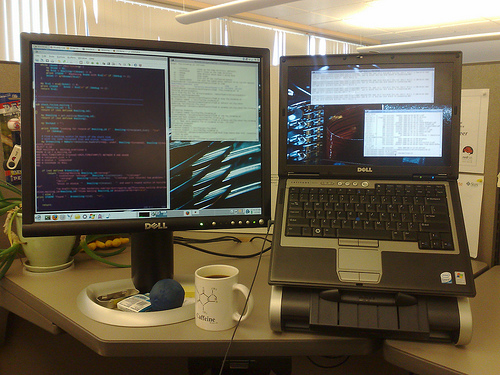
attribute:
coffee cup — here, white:
[194, 264, 254, 331]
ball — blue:
[149, 283, 182, 308]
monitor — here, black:
[20, 32, 272, 287]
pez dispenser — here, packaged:
[1, 92, 30, 185]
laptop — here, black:
[276, 54, 476, 294]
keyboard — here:
[286, 182, 451, 252]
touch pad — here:
[337, 249, 380, 270]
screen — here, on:
[291, 66, 447, 170]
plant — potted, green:
[3, 180, 132, 282]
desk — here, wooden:
[3, 214, 497, 375]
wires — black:
[150, 226, 497, 282]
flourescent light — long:
[332, 4, 493, 33]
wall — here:
[4, 63, 494, 261]